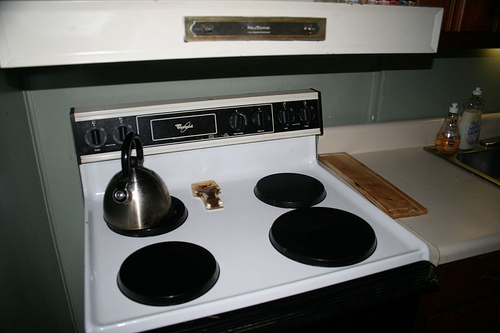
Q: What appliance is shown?
A: A stove.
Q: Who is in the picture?
A: No one.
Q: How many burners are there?
A: 4.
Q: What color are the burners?
A: Black.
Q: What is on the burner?
A: A teapot.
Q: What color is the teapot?
A: Silver.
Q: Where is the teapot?
A: On a burner.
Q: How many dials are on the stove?
A: 6.